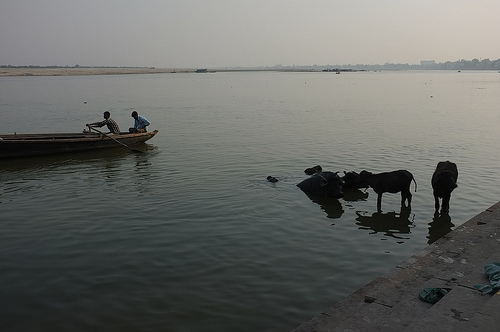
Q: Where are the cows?
A: In the water.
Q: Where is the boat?
A: In the water.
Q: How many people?
A: 2.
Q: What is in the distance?
A: Trees.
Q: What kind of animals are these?
A: Cows.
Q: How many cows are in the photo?
A: Two.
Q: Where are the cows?
A: In the water.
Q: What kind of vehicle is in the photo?
A: Canoe.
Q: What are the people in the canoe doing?
A: Rowing.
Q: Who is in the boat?
A: A couple men.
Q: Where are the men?
A: In water.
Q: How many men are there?
A: Two.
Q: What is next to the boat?
A: Animals.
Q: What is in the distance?
A: Land.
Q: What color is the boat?
A: Brown.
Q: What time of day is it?
A: Evening.